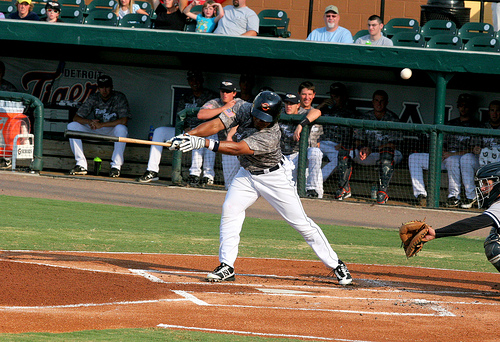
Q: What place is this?
A: It is a field.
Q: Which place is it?
A: It is a field.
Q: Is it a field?
A: Yes, it is a field.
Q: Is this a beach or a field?
A: It is a field.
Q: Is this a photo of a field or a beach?
A: It is showing a field.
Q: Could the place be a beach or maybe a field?
A: It is a field.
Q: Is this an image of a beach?
A: No, the picture is showing a field.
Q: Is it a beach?
A: No, it is a field.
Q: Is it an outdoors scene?
A: Yes, it is outdoors.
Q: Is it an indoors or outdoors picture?
A: It is outdoors.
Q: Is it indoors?
A: No, it is outdoors.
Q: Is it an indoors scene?
A: No, it is outdoors.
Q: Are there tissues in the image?
A: No, there are no tissues.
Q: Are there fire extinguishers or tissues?
A: No, there are no tissues or fire extinguishers.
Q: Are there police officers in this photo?
A: No, there are no police officers.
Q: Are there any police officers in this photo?
A: No, there are no police officers.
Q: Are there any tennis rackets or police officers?
A: No, there are no police officers or tennis rackets.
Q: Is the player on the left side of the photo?
A: Yes, the player is on the left of the image.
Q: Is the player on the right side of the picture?
A: No, the player is on the left of the image.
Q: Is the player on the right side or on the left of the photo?
A: The player is on the left of the image.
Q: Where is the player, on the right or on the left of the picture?
A: The player is on the left of the image.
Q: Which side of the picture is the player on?
A: The player is on the left of the image.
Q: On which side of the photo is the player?
A: The player is on the left of the image.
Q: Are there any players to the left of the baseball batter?
A: Yes, there is a player to the left of the batter.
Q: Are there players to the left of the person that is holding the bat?
A: Yes, there is a player to the left of the batter.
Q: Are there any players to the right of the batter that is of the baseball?
A: No, the player is to the left of the batter.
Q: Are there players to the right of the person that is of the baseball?
A: No, the player is to the left of the batter.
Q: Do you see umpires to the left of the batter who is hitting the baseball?
A: No, there is a player to the left of the batter.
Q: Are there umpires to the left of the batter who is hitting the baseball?
A: No, there is a player to the left of the batter.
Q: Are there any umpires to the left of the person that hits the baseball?
A: No, there is a player to the left of the batter.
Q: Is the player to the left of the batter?
A: Yes, the player is to the left of the batter.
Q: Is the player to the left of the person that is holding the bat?
A: Yes, the player is to the left of the batter.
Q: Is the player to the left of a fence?
A: No, the player is to the left of the batter.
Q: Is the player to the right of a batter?
A: No, the player is to the left of a batter.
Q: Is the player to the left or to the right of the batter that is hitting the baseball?
A: The player is to the left of the batter.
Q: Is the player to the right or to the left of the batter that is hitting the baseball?
A: The player is to the left of the batter.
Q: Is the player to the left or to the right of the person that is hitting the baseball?
A: The player is to the left of the batter.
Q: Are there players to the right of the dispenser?
A: Yes, there is a player to the right of the dispenser.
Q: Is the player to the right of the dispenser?
A: Yes, the player is to the right of the dispenser.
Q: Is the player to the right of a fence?
A: No, the player is to the right of the dispenser.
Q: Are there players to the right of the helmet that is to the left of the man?
A: No, the player is to the left of the helmet.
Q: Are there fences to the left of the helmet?
A: No, there is a player to the left of the helmet.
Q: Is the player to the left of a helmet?
A: Yes, the player is to the left of a helmet.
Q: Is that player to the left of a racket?
A: No, the player is to the left of a helmet.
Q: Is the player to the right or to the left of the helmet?
A: The player is to the left of the helmet.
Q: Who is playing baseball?
A: The batter is playing baseball.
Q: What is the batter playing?
A: The batter is playing baseball.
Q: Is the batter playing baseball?
A: Yes, the batter is playing baseball.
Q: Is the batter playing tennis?
A: No, the batter is playing baseball.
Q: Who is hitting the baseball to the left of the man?
A: The batter is hitting the baseball.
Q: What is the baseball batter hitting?
A: The batter is hitting the baseball.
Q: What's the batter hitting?
A: The batter is hitting the baseball.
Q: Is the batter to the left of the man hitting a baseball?
A: Yes, the batter is hitting a baseball.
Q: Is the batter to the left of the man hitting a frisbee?
A: No, the batter is hitting a baseball.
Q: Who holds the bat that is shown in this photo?
A: The batter holds the bat.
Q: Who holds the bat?
A: The batter holds the bat.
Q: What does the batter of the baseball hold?
A: The batter holds the bat.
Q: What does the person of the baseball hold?
A: The batter holds the bat.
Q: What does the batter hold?
A: The batter holds the bat.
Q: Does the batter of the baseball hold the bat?
A: Yes, the batter holds the bat.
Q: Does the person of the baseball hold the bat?
A: Yes, the batter holds the bat.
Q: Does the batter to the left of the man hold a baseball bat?
A: No, the batter holds the bat.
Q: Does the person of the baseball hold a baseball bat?
A: No, the batter holds the bat.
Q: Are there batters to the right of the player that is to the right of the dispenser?
A: Yes, there is a batter to the right of the player.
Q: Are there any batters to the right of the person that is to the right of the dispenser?
A: Yes, there is a batter to the right of the player.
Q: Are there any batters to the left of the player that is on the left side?
A: No, the batter is to the right of the player.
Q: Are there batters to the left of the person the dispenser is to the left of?
A: No, the batter is to the right of the player.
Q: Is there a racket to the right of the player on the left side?
A: No, there is a batter to the right of the player.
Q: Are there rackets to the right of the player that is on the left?
A: No, there is a batter to the right of the player.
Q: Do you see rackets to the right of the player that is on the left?
A: No, there is a batter to the right of the player.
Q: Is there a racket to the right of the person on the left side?
A: No, there is a batter to the right of the player.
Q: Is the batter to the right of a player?
A: Yes, the batter is to the right of a player.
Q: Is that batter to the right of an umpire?
A: No, the batter is to the right of a player.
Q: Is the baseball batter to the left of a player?
A: No, the batter is to the right of a player.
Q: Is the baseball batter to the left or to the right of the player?
A: The batter is to the right of the player.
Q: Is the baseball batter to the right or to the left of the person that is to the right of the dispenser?
A: The batter is to the right of the player.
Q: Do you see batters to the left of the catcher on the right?
A: Yes, there is a batter to the left of the catcher.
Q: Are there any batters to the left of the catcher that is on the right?
A: Yes, there is a batter to the left of the catcher.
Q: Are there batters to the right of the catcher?
A: No, the batter is to the left of the catcher.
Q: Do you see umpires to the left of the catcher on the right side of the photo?
A: No, there is a batter to the left of the catcher.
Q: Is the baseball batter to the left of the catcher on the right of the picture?
A: Yes, the batter is to the left of the catcher.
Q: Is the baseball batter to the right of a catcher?
A: No, the batter is to the left of a catcher.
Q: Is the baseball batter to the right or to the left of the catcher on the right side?
A: The batter is to the left of the catcher.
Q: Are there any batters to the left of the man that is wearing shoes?
A: Yes, there is a batter to the left of the man.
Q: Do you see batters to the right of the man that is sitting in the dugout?
A: No, the batter is to the left of the man.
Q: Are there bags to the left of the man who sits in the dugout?
A: No, there is a batter to the left of the man.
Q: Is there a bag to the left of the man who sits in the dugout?
A: No, there is a batter to the left of the man.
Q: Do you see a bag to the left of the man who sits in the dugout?
A: No, there is a batter to the left of the man.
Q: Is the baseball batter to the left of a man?
A: Yes, the batter is to the left of a man.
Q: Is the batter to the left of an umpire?
A: No, the batter is to the left of a man.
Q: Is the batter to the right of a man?
A: No, the batter is to the left of a man.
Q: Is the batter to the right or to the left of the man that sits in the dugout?
A: The batter is to the left of the man.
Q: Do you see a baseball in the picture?
A: Yes, there is a baseball.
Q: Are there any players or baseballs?
A: Yes, there is a baseball.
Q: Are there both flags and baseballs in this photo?
A: No, there is a baseball but no flags.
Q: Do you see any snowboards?
A: No, there are no snowboards.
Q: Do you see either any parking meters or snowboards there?
A: No, there are no snowboards or parking meters.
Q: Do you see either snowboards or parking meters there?
A: No, there are no snowboards or parking meters.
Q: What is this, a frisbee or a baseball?
A: This is a baseball.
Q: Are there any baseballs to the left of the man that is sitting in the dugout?
A: Yes, there is a baseball to the left of the man.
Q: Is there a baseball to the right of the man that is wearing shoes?
A: No, the baseball is to the left of the man.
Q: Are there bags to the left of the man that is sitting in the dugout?
A: No, there is a baseball to the left of the man.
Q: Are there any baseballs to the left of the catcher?
A: Yes, there is a baseball to the left of the catcher.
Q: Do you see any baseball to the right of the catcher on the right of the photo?
A: No, the baseball is to the left of the catcher.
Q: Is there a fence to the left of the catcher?
A: No, there is a baseball to the left of the catcher.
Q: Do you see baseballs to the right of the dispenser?
A: Yes, there is a baseball to the right of the dispenser.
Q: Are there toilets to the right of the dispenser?
A: No, there is a baseball to the right of the dispenser.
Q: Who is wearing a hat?
A: The man is wearing a hat.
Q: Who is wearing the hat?
A: The man is wearing a hat.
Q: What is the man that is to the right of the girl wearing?
A: The man is wearing a hat.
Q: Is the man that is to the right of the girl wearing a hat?
A: Yes, the man is wearing a hat.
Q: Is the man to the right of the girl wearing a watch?
A: No, the man is wearing a hat.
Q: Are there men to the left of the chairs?
A: Yes, there is a man to the left of the chairs.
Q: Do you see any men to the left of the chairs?
A: Yes, there is a man to the left of the chairs.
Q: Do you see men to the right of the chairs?
A: No, the man is to the left of the chairs.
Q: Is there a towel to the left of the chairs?
A: No, there is a man to the left of the chairs.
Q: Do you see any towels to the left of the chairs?
A: No, there is a man to the left of the chairs.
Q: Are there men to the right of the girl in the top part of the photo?
A: Yes, there is a man to the right of the girl.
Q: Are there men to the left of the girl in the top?
A: No, the man is to the right of the girl.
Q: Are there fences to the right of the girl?
A: No, there is a man to the right of the girl.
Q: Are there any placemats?
A: No, there are no placemats.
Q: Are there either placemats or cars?
A: No, there are no placemats or cars.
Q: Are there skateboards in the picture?
A: No, there are no skateboards.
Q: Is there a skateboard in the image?
A: No, there are no skateboards.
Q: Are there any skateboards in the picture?
A: No, there are no skateboards.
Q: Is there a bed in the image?
A: No, there are no beds.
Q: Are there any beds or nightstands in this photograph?
A: No, there are no beds or nightstands.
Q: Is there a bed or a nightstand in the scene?
A: No, there are no beds or nightstands.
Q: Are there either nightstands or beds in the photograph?
A: No, there are no beds or nightstands.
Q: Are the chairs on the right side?
A: Yes, the chairs are on the right of the image.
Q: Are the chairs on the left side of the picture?
A: No, the chairs are on the right of the image.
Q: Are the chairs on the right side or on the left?
A: The chairs are on the right of the image.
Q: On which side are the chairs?
A: The chairs are on the right of the image.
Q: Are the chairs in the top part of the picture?
A: Yes, the chairs are in the top of the image.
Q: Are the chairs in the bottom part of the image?
A: No, the chairs are in the top of the image.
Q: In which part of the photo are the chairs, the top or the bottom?
A: The chairs are in the top of the image.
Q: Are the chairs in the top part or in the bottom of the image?
A: The chairs are in the top of the image.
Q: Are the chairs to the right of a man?
A: Yes, the chairs are to the right of a man.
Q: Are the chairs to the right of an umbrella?
A: No, the chairs are to the right of a man.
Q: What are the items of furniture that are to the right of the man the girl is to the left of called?
A: The pieces of furniture are chairs.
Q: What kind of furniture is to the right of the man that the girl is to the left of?
A: The pieces of furniture are chairs.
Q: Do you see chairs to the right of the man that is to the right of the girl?
A: Yes, there are chairs to the right of the man.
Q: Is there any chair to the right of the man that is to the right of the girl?
A: Yes, there are chairs to the right of the man.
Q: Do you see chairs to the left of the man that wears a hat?
A: No, the chairs are to the right of the man.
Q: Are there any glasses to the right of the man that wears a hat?
A: No, there are chairs to the right of the man.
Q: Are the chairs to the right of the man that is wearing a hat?
A: Yes, the chairs are to the right of the man.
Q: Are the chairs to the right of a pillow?
A: No, the chairs are to the right of the man.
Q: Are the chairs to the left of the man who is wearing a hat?
A: No, the chairs are to the right of the man.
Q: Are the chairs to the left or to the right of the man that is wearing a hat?
A: The chairs are to the right of the man.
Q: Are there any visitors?
A: No, there are no visitors.